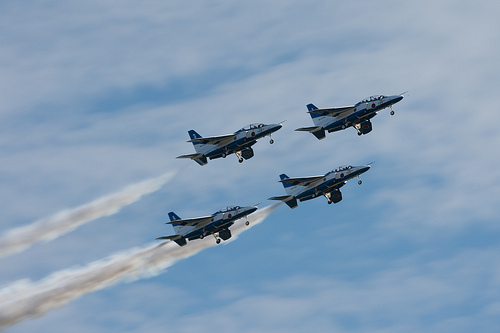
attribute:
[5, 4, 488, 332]
sky — partial, blue, cloudy, overcast, clear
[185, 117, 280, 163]
airplane — flying, gray, pointy, navy, blue, fighter jet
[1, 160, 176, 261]
smoke — thick, dirty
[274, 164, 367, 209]
airplane — in a cluster, flying in formation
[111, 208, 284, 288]
smoke — black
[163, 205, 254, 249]
airplane — jet, flying in formation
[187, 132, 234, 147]
wing — on the right, on side of plane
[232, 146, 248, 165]
wheel — in the front, rear of plane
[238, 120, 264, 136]
cockpit — glass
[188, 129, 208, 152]
tail — blue, triangular, partial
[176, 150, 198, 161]
hind wing — partial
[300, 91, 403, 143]
airplane — navy, flying in formation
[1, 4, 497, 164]
cloud — white, thin, partial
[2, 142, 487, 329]
cloud — soft, white, partial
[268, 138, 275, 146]
tire — large, rubber, black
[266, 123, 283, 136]
nose — partial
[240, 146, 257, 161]
landing gear — capped, black